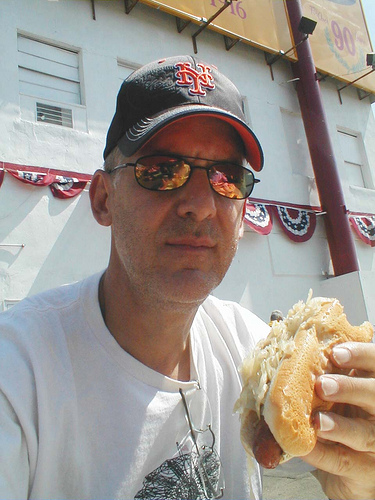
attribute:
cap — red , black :
[91, 53, 268, 174]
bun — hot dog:
[238, 289, 353, 469]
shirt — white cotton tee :
[6, 276, 359, 495]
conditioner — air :
[28, 91, 89, 129]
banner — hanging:
[258, 196, 365, 253]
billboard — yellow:
[207, 12, 353, 82]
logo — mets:
[166, 53, 235, 114]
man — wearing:
[46, 49, 328, 457]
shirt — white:
[39, 265, 319, 477]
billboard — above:
[190, 8, 372, 63]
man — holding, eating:
[58, 68, 301, 455]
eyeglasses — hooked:
[161, 374, 239, 481]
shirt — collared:
[35, 270, 286, 496]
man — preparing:
[63, 81, 264, 421]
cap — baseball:
[121, 76, 267, 157]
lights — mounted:
[283, 22, 319, 62]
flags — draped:
[246, 184, 349, 249]